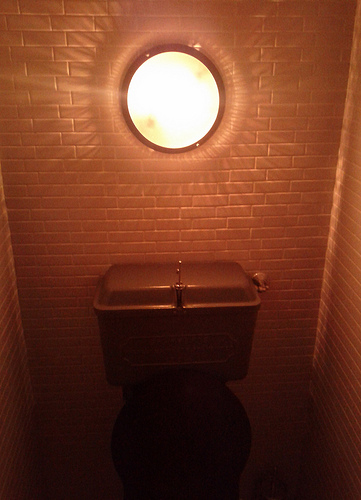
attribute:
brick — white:
[21, 31, 66, 46]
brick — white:
[26, 62, 67, 75]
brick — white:
[13, 77, 56, 92]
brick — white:
[16, 106, 59, 119]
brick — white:
[19, 132, 60, 146]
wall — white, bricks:
[239, 185, 356, 222]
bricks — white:
[229, 216, 297, 239]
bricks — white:
[267, 262, 317, 313]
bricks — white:
[249, 360, 304, 382]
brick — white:
[29, 89, 72, 102]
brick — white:
[74, 144, 112, 161]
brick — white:
[268, 143, 305, 155]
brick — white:
[274, 62, 312, 72]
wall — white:
[4, 46, 360, 429]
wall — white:
[0, 0, 356, 433]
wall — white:
[270, 98, 344, 354]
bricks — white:
[0, 0, 360, 497]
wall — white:
[1, 1, 360, 498]